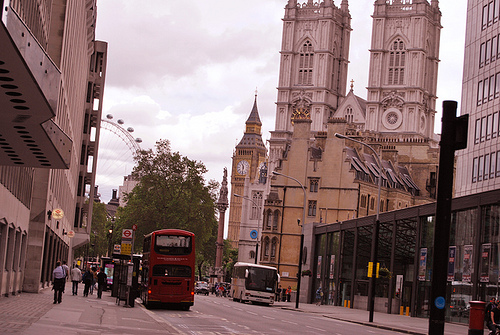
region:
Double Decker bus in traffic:
[140, 225, 201, 312]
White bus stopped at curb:
[226, 261, 284, 307]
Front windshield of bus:
[243, 267, 283, 294]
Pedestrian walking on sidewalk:
[46, 259, 72, 306]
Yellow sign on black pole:
[361, 258, 387, 281]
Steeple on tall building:
[234, 88, 267, 150]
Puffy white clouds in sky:
[195, 71, 242, 93]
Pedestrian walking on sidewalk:
[68, 261, 85, 296]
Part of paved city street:
[209, 308, 244, 328]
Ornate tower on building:
[363, 2, 445, 93]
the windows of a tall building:
[0, 211, 28, 286]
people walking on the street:
[41, 261, 89, 302]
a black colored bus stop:
[114, 238, 151, 298]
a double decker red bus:
[140, 225, 201, 306]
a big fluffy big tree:
[138, 149, 199, 219]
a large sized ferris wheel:
[97, 112, 148, 169]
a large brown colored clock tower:
[230, 105, 271, 229]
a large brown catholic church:
[260, 35, 414, 262]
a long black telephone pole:
[417, 62, 475, 316]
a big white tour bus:
[211, 255, 279, 313]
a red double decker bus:
[130, 209, 205, 318]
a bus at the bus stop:
[97, 202, 207, 332]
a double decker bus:
[140, 226, 197, 306]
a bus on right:
[229, 260, 279, 306]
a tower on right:
[229, 79, 268, 257]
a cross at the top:
[348, 74, 357, 87]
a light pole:
[229, 130, 383, 322]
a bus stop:
[109, 249, 140, 309]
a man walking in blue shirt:
[49, 260, 69, 305]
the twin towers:
[238, 0, 443, 257]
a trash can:
[467, 295, 487, 333]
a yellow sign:
[118, 240, 135, 254]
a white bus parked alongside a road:
[228, 258, 284, 308]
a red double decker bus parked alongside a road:
[137, 225, 201, 313]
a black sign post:
[424, 98, 460, 333]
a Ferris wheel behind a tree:
[98, 115, 150, 164]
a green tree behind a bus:
[110, 150, 215, 268]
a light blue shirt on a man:
[50, 263, 67, 277]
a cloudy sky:
[89, 0, 468, 201]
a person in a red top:
[284, 285, 295, 302]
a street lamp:
[331, 129, 389, 325]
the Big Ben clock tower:
[224, 90, 267, 263]